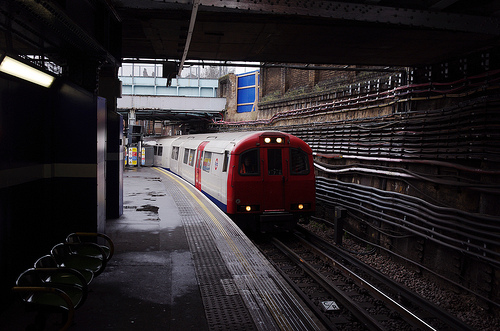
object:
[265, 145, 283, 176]
window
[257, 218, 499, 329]
tracks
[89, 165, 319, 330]
platform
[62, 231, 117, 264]
empty seats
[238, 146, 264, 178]
window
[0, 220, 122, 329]
seating area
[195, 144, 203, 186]
doors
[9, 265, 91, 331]
chairs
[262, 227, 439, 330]
some tracks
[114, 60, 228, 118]
bridge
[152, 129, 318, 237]
train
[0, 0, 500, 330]
station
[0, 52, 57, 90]
tube light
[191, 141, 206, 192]
door panel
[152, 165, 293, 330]
line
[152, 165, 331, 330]
edge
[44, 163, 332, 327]
platform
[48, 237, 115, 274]
seat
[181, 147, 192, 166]
windows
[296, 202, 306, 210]
light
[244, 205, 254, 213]
light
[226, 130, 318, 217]
front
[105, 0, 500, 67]
ceiling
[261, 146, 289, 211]
door